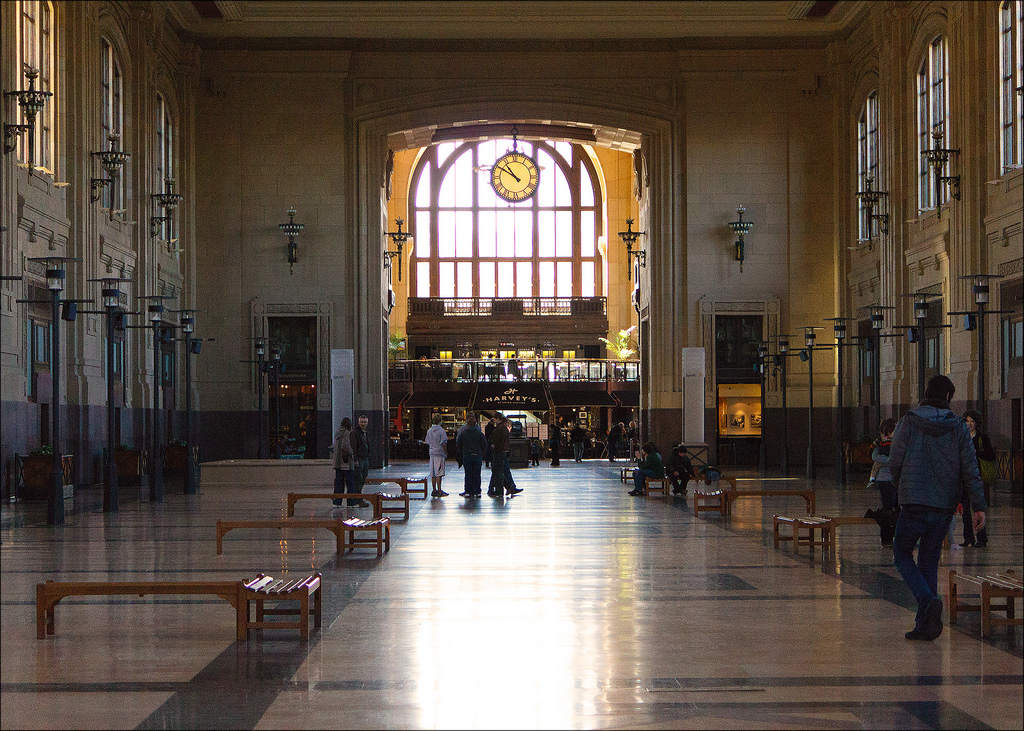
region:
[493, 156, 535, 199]
A clock suspended from the ceiling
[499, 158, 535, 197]
A clock in front of the window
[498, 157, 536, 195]
A clock above the floor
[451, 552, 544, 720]
Window reflecting light on the floor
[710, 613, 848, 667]
A well polished terrazo floor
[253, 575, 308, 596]
A bench set on the floor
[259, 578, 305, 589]
Reflection of light on the bench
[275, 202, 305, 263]
A light fixture mounted on the wall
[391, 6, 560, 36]
The ceiling of the building above the people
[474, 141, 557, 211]
clock in front of window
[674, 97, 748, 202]
white brick on wall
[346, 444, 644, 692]
light shining on floor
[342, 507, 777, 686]
floor is light grey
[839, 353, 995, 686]
person walking on floor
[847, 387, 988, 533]
person has grey coat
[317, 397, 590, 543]
people gathered in distance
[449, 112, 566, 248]
black hands on clock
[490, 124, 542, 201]
clock hanging from ceiling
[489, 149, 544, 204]
clock reads 10:50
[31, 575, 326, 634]
short bench in train station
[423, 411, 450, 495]
person wearing white shorts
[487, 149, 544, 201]
clock hanging from ceiling is yellow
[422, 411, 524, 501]
people gathered in middle of room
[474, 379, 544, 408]
harvey's restaurant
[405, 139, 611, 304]
sun shining through the window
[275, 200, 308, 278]
decorative light hanging on wall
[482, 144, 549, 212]
the clock on a window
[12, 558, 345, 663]
a bench of wood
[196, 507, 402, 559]
a bench of wood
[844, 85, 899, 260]
the window on a church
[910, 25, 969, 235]
the window on a church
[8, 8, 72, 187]
the window on a church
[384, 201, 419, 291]
a cross on the left side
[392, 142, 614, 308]
the window is large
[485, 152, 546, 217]
the clock is golden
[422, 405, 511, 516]
the people are standing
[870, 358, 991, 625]
the man is walking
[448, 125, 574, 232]
a clock on a window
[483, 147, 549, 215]
the clock is yellow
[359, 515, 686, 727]
sunlight on the floor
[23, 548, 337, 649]
the bench is wood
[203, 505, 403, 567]
the bench is wood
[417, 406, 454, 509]
person wears white clothes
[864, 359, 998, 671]
person has a gray long sleeve shirt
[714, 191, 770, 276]
a light on the wall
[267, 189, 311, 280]
a light on the wall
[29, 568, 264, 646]
a long wooden bench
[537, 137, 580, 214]
a window on a building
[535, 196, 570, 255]
a window on a building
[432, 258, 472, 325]
a window on a building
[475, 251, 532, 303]
a window on a building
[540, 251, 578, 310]
a window on a building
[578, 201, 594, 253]
a window on a building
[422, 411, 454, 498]
man wearing gray sweatshirt